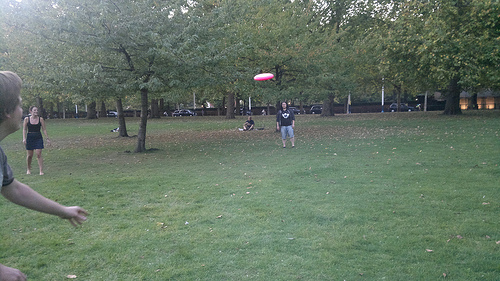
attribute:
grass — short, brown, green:
[0, 110, 497, 278]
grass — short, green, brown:
[198, 182, 363, 232]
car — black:
[387, 101, 416, 111]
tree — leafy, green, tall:
[57, 8, 192, 160]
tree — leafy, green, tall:
[393, 9, 476, 124]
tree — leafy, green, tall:
[266, 20, 384, 137]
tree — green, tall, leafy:
[8, 0, 268, 156]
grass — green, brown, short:
[321, 134, 476, 269]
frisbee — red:
[253, 72, 276, 79]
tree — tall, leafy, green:
[412, 0, 474, 120]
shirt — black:
[277, 107, 295, 127]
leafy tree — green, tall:
[77, 2, 187, 150]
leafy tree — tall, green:
[288, 0, 374, 116]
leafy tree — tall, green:
[402, 0, 496, 113]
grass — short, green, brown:
[140, 134, 499, 236]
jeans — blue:
[268, 122, 320, 157]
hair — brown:
[0, 71, 24, 121]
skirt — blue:
[25, 130, 44, 150]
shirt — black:
[20, 105, 57, 151]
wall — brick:
[118, 55, 489, 173]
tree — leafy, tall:
[10, 12, 238, 144]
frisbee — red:
[253, 72, 273, 81]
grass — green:
[180, 126, 324, 243]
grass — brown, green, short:
[57, 116, 498, 278]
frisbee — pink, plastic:
[243, 60, 285, 85]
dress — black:
[25, 115, 45, 152]